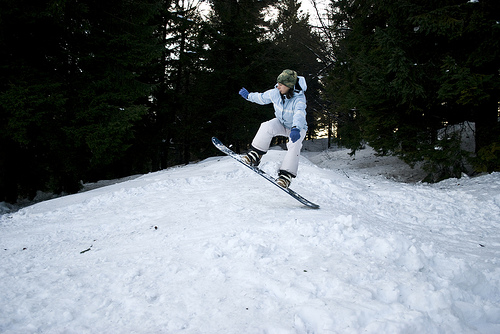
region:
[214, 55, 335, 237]
a person riding a snowboard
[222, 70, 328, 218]
a person performing a trick on a snowboard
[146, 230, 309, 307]
white snow of the hill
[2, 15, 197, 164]
green trees growing next to the ski slope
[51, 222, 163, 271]
brown twigs in the snow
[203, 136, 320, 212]
blue and black snowboard in midair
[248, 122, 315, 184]
the woman's white snow pants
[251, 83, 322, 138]
the woman's blue jacket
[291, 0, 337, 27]
white cloudy skies behind the trees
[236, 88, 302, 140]
the woman's dark blue gloves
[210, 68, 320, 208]
the person on a snowboard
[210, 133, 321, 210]
the snowboard under the person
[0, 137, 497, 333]
the snow on the ground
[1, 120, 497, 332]
the marks on the snow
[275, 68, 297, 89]
the beanie on the person's head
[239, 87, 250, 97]
the glove on the person's hand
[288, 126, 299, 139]
the glove on the person's hand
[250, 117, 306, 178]
the pants on the person snowboarding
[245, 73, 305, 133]
the jacket on the person snowboarding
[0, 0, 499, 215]
the trees behind the person snowboarding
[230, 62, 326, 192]
girl is on snowboard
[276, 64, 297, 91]
girl has camouflage cap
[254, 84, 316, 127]
girl has light blue coat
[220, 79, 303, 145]
girl has blue gloves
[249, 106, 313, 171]
girl has white pants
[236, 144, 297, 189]
girl has black shoes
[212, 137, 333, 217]
girl on blue snowboard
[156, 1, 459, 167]
green trees behind girl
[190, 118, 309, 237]
nose of snowboard is raised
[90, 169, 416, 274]
snow is white and packed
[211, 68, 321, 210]
Snowboarder performing a trick.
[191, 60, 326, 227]
a snowboarder on a snowy slope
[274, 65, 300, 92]
the person has a knit hat on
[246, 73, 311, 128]
the down jacket with a hoodie is blue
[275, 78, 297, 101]
the girl has long dark hair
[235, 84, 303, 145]
the snowboarder's gloves are blue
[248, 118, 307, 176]
white down ski pants are on the girl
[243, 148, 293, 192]
snowboard boots are on the board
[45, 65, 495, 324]
the snowboarder is jumping over a mound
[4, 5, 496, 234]
evergreen trees are behind the girl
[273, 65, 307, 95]
the knit hat is green and beige